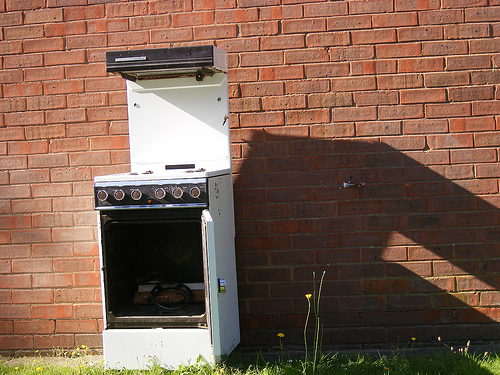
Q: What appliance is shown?
A: Oven/stove.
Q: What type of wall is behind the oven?
A: Brick.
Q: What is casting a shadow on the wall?
A: Oven.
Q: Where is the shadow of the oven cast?
A: The wall.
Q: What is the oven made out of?
A: Metal.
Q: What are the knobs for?
A: The burners.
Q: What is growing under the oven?
A: Grass.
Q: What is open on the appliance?
A: Oven door.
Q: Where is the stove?
A: In front of the wall.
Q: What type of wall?
A: Bricks.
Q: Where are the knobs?
A: Stove.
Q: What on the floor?
A: Grass.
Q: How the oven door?
A: Open.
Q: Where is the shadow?
A: Next to the oven.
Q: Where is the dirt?
A: Next to the oven.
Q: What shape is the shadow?
A: Oven.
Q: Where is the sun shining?
A: On the oven.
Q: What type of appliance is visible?
A: Stove.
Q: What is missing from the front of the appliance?
A: Door.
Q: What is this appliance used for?
A: Cooking.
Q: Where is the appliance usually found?
A: Kitchen.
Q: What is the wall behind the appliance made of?
A: Brick.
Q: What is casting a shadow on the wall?
A: Stove.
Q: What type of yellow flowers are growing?
A: Dandelions.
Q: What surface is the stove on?
A: Concrete.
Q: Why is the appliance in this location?
A: It's broken.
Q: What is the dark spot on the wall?
A: Shadow.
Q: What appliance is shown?
A: Oven.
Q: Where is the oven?
A: Outside against a wall.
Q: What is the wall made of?
A: Brick.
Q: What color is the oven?
A: White.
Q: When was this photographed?
A: Day time.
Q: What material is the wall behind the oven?
A: Brick.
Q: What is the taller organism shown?
A: Dandelion.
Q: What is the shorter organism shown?
A: Grass.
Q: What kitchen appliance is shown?
A: Oven.